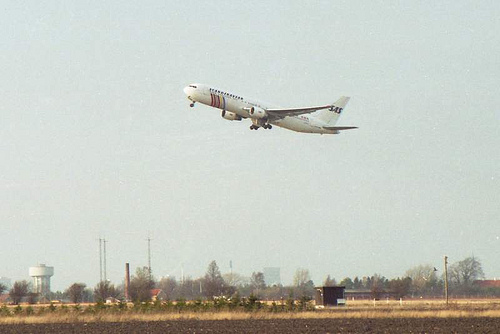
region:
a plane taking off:
[159, 75, 406, 142]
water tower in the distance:
[22, 255, 69, 311]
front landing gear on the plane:
[182, 94, 202, 119]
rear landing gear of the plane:
[242, 115, 278, 140]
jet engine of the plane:
[245, 104, 271, 121]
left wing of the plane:
[249, 102, 337, 124]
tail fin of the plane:
[313, 90, 358, 116]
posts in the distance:
[85, 234, 115, 298]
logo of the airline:
[323, 99, 348, 119]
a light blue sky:
[0, 7, 495, 237]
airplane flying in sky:
[185, 81, 354, 138]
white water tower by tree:
[28, 261, 54, 293]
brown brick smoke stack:
[124, 262, 130, 302]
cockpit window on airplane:
[188, 82, 196, 89]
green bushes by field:
[5, 295, 277, 314]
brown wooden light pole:
[442, 256, 451, 306]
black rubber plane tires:
[251, 122, 273, 131]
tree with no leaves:
[450, 255, 485, 287]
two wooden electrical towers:
[98, 235, 108, 290]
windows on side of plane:
[206, 88, 241, 101]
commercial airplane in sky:
[164, 71, 358, 163]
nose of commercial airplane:
[181, 80, 216, 105]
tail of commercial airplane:
[326, 87, 356, 119]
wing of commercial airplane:
[291, 97, 332, 117]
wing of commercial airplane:
[333, 122, 354, 137]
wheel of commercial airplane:
[261, 122, 274, 129]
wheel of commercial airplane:
[180, 102, 201, 109]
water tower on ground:
[13, 254, 63, 301]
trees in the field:
[183, 286, 251, 319]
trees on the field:
[75, 298, 117, 310]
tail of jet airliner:
[313, 84, 364, 141]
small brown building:
[309, 279, 354, 310]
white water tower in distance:
[21, 258, 62, 301]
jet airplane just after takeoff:
[178, 70, 375, 152]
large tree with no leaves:
[439, 248, 488, 303]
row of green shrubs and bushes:
[105, 296, 303, 316]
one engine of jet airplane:
[240, 103, 270, 120]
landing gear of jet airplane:
[246, 121, 276, 134]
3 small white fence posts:
[365, 291, 414, 311]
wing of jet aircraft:
[266, 99, 338, 120]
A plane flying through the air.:
[156, 50, 381, 180]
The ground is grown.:
[152, 315, 402, 330]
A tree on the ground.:
[200, 246, 226, 297]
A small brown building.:
[308, 276, 346, 316]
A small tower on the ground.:
[22, 255, 60, 300]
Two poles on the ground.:
[90, 225, 113, 310]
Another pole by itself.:
[117, 255, 137, 310]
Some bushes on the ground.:
[61, 291, 294, 312]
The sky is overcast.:
[35, 55, 125, 171]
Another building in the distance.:
[471, 275, 498, 293]